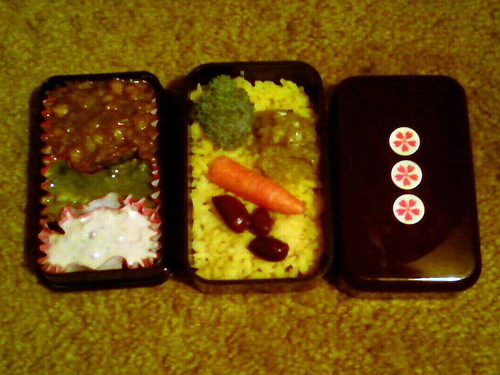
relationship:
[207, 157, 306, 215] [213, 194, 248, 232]
carrot beside olive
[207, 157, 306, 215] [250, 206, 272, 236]
carrot beside olive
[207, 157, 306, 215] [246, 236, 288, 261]
carrot beside olive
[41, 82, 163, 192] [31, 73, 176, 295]
beans in dish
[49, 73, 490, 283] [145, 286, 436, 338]
trays on carpet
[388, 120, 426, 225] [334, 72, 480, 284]
white decal on lid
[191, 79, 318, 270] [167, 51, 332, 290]
rice in container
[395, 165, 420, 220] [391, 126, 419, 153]
flowers on decal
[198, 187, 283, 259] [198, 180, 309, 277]
three olives on rice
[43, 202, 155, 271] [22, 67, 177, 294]
white sauce on container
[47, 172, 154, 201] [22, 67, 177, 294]
sauce in container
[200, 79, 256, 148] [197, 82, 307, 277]
item on rice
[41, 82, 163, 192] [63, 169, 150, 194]
beans has sauce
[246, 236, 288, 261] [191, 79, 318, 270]
olive on rice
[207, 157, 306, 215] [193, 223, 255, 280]
carrot on rice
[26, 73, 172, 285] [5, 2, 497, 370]
container on table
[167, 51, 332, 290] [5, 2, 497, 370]
container on table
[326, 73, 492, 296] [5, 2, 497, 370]
container on table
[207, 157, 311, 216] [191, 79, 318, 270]
carrot on top of rice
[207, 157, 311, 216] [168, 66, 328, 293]
carrot in dish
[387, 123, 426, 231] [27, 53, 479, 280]
circles on top of container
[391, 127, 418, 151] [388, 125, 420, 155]
flower in circle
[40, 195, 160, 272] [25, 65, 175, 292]
food in bowl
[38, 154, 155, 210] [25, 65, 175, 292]
food in bowl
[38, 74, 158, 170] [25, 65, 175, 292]
food in bowl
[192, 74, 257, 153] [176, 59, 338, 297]
food in bowl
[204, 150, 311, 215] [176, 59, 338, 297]
food in bowl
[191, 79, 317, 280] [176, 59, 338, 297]
rice in bowl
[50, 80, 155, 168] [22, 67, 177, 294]
beans soup in container